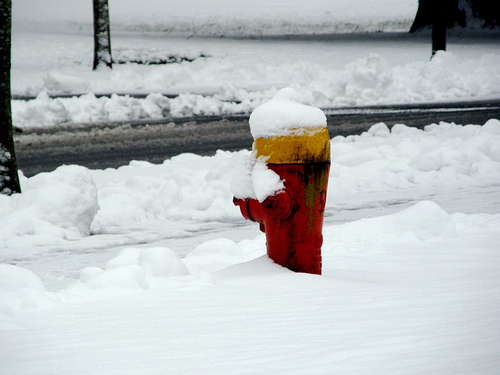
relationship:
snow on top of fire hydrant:
[248, 89, 325, 136] [236, 124, 332, 277]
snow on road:
[24, 86, 257, 201] [38, 88, 499, 147]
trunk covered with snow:
[93, 10, 125, 76] [96, 28, 110, 61]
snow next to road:
[24, 86, 257, 201] [38, 88, 499, 147]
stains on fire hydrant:
[290, 157, 335, 190] [236, 124, 332, 277]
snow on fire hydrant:
[248, 89, 325, 136] [236, 124, 332, 277]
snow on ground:
[24, 86, 257, 201] [29, 59, 499, 374]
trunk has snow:
[93, 10, 125, 76] [96, 28, 110, 61]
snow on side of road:
[24, 86, 257, 201] [38, 88, 499, 147]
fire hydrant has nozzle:
[236, 124, 332, 277] [263, 188, 303, 234]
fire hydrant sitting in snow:
[236, 124, 332, 277] [32, 230, 500, 371]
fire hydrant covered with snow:
[236, 124, 332, 277] [248, 89, 325, 136]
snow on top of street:
[24, 86, 257, 201] [38, 88, 499, 147]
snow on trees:
[96, 28, 110, 61] [3, 9, 141, 122]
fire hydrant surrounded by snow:
[236, 124, 332, 277] [32, 230, 500, 371]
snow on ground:
[32, 230, 500, 371] [29, 59, 499, 374]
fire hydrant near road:
[236, 124, 332, 277] [38, 88, 499, 147]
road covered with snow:
[38, 88, 499, 147] [24, 86, 257, 201]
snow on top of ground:
[24, 86, 257, 201] [29, 59, 499, 374]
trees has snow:
[3, 9, 141, 122] [96, 28, 110, 61]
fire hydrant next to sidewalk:
[236, 124, 332, 277] [23, 90, 497, 128]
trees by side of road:
[3, 9, 141, 122] [38, 88, 499, 147]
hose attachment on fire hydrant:
[228, 181, 292, 225] [236, 124, 332, 277]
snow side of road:
[24, 86, 257, 201] [38, 88, 499, 147]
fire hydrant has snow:
[236, 124, 332, 277] [248, 89, 325, 136]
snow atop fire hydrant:
[248, 89, 325, 136] [236, 124, 332, 277]